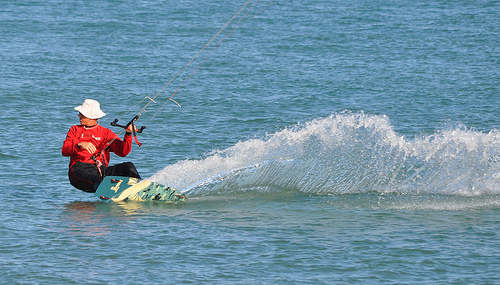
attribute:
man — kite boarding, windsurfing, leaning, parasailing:
[65, 94, 142, 192]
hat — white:
[73, 98, 106, 119]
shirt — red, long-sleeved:
[61, 123, 134, 168]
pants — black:
[69, 160, 143, 193]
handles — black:
[110, 114, 146, 133]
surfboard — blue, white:
[94, 172, 184, 202]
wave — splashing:
[144, 107, 499, 214]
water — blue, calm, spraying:
[2, 1, 500, 284]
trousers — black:
[68, 163, 142, 192]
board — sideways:
[93, 175, 188, 206]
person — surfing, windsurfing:
[62, 99, 142, 192]